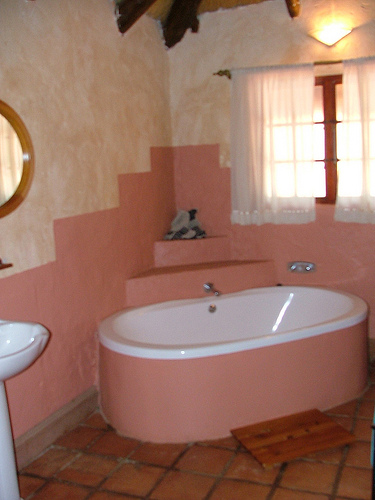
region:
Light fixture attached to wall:
[300, 18, 355, 48]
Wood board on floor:
[229, 401, 355, 463]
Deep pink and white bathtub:
[91, 277, 372, 446]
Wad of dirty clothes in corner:
[164, 203, 214, 238]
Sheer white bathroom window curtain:
[227, 65, 316, 227]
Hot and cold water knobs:
[287, 257, 313, 274]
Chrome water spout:
[197, 280, 226, 297]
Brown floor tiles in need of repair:
[42, 435, 174, 488]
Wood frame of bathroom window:
[315, 72, 343, 204]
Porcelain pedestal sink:
[1, 319, 49, 499]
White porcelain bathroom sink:
[0, 303, 57, 497]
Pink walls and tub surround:
[0, 151, 374, 422]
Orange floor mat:
[231, 407, 360, 474]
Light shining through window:
[244, 78, 373, 200]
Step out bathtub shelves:
[119, 223, 281, 297]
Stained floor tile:
[11, 403, 372, 496]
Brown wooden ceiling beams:
[105, 0, 298, 46]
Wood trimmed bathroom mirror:
[0, 82, 39, 238]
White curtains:
[207, 49, 374, 231]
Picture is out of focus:
[2, 1, 372, 495]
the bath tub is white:
[123, 287, 346, 345]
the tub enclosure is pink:
[107, 333, 372, 426]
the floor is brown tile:
[57, 452, 231, 499]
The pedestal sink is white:
[1, 319, 52, 498]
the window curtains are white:
[225, 62, 374, 224]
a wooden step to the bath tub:
[226, 405, 354, 468]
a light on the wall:
[288, 12, 368, 46]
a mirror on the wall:
[0, 98, 39, 215]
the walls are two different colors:
[43, 93, 218, 213]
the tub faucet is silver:
[201, 279, 222, 315]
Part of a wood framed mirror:
[1, 79, 47, 236]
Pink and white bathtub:
[100, 288, 373, 398]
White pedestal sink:
[0, 319, 60, 498]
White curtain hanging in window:
[225, 56, 321, 228]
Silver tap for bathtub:
[192, 272, 230, 312]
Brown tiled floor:
[62, 440, 199, 499]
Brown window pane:
[308, 68, 350, 228]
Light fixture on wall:
[285, 18, 360, 56]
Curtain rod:
[194, 52, 368, 86]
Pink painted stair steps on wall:
[46, 135, 176, 266]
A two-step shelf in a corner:
[123, 220, 274, 296]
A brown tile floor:
[87, 444, 219, 496]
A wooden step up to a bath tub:
[220, 408, 352, 464]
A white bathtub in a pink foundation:
[83, 281, 373, 403]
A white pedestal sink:
[4, 309, 53, 416]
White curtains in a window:
[224, 82, 319, 226]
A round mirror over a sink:
[0, 97, 41, 202]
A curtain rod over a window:
[198, 55, 366, 78]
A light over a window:
[308, 12, 352, 53]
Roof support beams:
[104, 5, 207, 49]